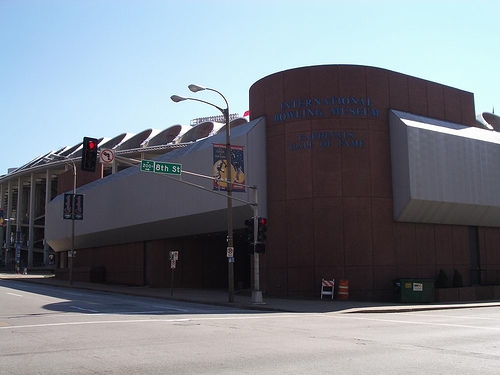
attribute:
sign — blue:
[13, 240, 23, 257]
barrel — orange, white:
[338, 278, 350, 299]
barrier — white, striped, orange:
[308, 277, 390, 324]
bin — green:
[387, 273, 437, 304]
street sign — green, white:
[141, 158, 183, 175]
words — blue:
[278, 94, 375, 113]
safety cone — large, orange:
[331, 273, 353, 305]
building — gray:
[34, 61, 499, 299]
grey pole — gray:
[234, 185, 278, 289]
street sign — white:
[96, 146, 116, 167]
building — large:
[199, 75, 439, 293]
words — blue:
[285, 124, 366, 155]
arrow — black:
[98, 145, 114, 164]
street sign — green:
[140, 155, 185, 178]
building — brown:
[257, 81, 404, 289]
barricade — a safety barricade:
[311, 272, 357, 304]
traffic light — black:
[82, 137, 102, 175]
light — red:
[252, 211, 274, 231]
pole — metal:
[243, 205, 273, 308]